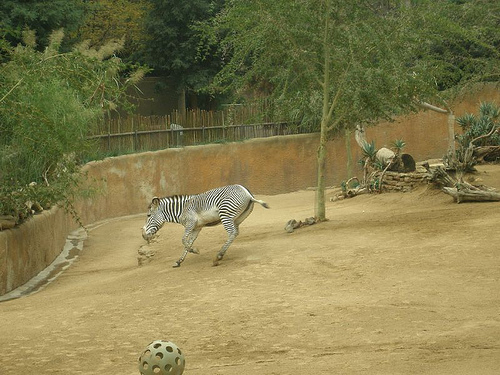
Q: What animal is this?
A: Zebra.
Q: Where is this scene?
A: A zoo.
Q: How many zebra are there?
A: 1.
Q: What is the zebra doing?
A: Running.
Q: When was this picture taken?
A: Daytime.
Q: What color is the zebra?
A: Black and white.